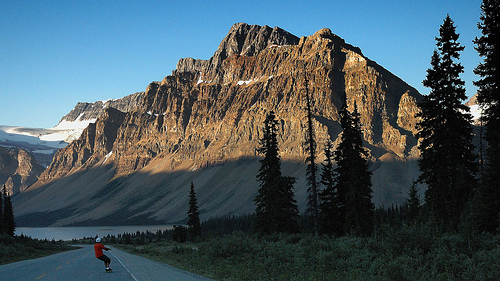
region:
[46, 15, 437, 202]
A large mountain in the background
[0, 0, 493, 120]
The sky is clear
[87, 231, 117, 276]
A person is on a skateboard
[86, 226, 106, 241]
Person is wearing a white helmet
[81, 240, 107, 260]
Person is wearing a red shirt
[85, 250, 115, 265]
Person is wearing shorts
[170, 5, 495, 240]
Pine trees in the background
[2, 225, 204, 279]
Person is skateboarding on the road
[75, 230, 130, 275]
A backview of a skateboarder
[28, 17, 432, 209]
Mountain is brown in color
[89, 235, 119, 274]
A skateboarder on the street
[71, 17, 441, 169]
A large mountain formation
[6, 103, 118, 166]
Snow in the mountains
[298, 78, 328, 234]
A tall tree with few branches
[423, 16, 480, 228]
A tree with many branches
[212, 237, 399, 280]
A group of small, low bushes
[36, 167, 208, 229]
A mountain slope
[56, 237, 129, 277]
A skateboarder on an empty road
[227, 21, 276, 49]
The peak of the mountain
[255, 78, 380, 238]
A cluster of trees together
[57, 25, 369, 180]
tall brown mountain in distance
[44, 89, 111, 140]
snow on base of mountain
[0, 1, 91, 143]
sky is blue and cloudless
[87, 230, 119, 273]
person is skating down hill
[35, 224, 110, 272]
yellow lines on light grey road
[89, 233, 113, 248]
person skating is wearing white helmet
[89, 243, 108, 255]
person on skateboard is wearing red shirt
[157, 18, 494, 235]
tall green pine trees next to skateboarder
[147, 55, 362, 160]
sun shines on most of mountain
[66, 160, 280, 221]
snow covers shadowed area of mountain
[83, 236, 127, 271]
person skate boarding on road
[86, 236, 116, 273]
man skate boarding on road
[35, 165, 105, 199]
brown and tan side of mountain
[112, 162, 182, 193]
brown and tan side of mountain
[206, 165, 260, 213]
brown and tan side of mountain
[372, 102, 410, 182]
brown and tan side of mountain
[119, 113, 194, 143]
brown and tan side of mountain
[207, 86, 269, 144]
brown and tan side of mountain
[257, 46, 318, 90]
brown and tan side of mountain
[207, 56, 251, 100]
brown and tan side of mountain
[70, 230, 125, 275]
A person skating down an empty road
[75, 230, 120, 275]
A person riding his skateboard on a road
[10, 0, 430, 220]
A large mountain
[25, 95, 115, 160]
A snow covered mountain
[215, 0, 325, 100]
The peak of a mountain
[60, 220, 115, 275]
A skater on an open road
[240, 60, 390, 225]
Trees along the road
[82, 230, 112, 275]
A person on his skateboard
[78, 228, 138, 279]
A skater speeding down the road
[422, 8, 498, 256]
Tall trees